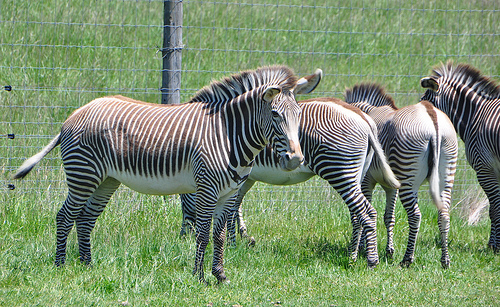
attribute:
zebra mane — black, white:
[189, 62, 299, 102]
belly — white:
[102, 166, 197, 200]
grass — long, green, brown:
[1, 0, 498, 305]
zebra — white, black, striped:
[72, 90, 279, 215]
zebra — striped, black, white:
[340, 80, 457, 270]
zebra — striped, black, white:
[13, 63, 322, 285]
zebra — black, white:
[32, 65, 328, 276]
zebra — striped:
[23, 59, 498, 284]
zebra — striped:
[222, 95, 405, 267]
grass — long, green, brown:
[2, 104, 498, 304]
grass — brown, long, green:
[266, 237, 322, 305]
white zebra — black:
[12, 61, 315, 283]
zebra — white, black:
[150, 76, 394, 277]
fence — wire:
[4, 1, 61, 259]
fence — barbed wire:
[0, 0, 499, 199]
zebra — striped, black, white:
[235, 94, 400, 270]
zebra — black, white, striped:
[45, 85, 316, 275]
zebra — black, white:
[162, 77, 407, 274]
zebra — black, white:
[419, 52, 499, 256]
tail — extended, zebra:
[14, 125, 59, 179]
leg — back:
[53, 165, 105, 266]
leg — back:
[74, 178, 119, 266]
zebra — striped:
[80, 88, 293, 223]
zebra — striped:
[80, 67, 320, 259]